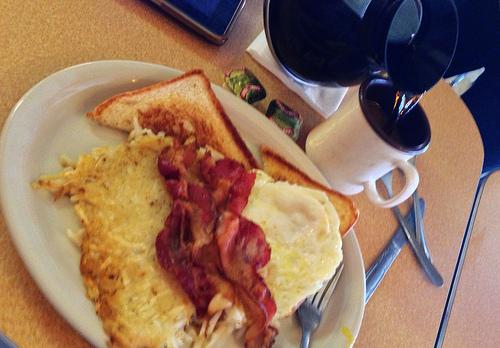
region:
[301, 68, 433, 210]
A white and brown coffee mug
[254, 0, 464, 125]
A black coffee pot pouring coffee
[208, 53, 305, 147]
Two packs of jelly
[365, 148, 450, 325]
Three pieces of silverware laying on table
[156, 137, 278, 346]
Two strips of brown bacon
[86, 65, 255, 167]
Half a piece of toast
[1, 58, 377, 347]
A full plate of breakfast food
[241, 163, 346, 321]
An over medium egg on a plate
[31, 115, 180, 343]
Hash browns on a plate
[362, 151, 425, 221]
A white coffee mug handle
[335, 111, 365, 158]
a white cup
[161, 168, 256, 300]
bacon on the sandwhich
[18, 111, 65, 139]
the plate is white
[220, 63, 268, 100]
butter on the table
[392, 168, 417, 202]
a handle on the cup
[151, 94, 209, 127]
grilled bread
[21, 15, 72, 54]
a brown countertop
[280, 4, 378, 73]
the coffee pot is black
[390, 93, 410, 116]
brown liquid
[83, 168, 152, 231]
hashbrowns on the plate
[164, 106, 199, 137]
the toast is brown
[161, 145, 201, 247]
the bacon is crispy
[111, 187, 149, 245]
the hashbrowns are light yellow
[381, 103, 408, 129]
the coffee is black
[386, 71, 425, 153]
the coffee is being poured into the cup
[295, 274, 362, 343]
the fork is on the plate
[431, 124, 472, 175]
the table is brown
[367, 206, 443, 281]
the utencils are on the table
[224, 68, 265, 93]
the package is green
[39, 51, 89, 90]
the plate is on the table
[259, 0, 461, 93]
The pot of coffee being poured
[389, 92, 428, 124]
The coffee pouring into the mug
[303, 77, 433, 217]
The mug of coffee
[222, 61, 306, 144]
Two packets of jelly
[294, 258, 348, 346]
The fork on the plate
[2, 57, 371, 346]
The plate the food is on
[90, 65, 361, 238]
The toast on the plate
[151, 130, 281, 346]
The two strips of bacon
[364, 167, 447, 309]
The silverware on the table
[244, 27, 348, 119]
The napkin near the jellies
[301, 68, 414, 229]
a black and white mug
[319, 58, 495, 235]
a black and white mug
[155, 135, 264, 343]
two strips of bacon